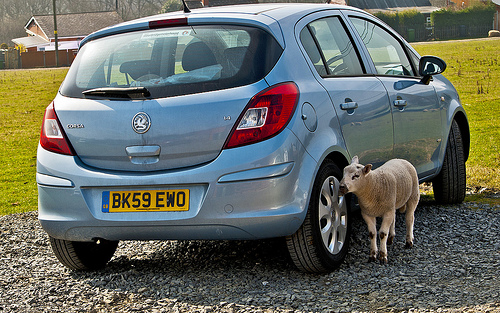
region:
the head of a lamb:
[333, 148, 378, 200]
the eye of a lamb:
[348, 170, 364, 182]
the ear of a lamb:
[360, 160, 378, 177]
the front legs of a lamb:
[357, 203, 397, 264]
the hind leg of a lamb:
[400, 187, 427, 237]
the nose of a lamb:
[336, 178, 351, 193]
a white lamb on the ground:
[332, 152, 429, 268]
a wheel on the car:
[282, 154, 365, 285]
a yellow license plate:
[92, 184, 194, 217]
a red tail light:
[222, 76, 303, 148]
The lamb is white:
[336, 147, 441, 270]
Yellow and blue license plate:
[83, 181, 201, 220]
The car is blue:
[36, 13, 478, 261]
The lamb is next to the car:
[33, 11, 478, 270]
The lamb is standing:
[325, 138, 445, 269]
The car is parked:
[26, 16, 483, 269]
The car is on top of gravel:
[19, 1, 484, 293]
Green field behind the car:
[39, 38, 484, 175]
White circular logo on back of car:
[128, 108, 161, 138]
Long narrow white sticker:
[138, 27, 202, 44]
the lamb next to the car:
[335, 152, 420, 268]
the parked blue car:
[34, 3, 471, 269]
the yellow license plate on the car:
[97, 187, 192, 215]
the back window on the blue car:
[59, 30, 279, 87]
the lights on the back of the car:
[35, 97, 302, 159]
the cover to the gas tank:
[294, 93, 324, 138]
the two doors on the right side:
[293, 1, 452, 176]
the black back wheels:
[40, 165, 360, 275]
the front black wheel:
[441, 122, 472, 210]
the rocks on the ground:
[388, 254, 469, 311]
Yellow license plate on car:
[108, 186, 195, 219]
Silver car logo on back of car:
[128, 111, 155, 136]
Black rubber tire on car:
[286, 239, 348, 272]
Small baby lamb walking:
[336, 158, 421, 268]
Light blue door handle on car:
[337, 96, 364, 117]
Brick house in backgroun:
[8, 12, 75, 66]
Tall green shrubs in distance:
[427, 6, 496, 38]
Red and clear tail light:
[228, 82, 305, 146]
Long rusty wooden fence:
[21, 51, 55, 66]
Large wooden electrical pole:
[52, 1, 59, 50]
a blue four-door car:
[28, 5, 470, 273]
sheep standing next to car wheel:
[277, 126, 425, 268]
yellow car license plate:
[100, 185, 192, 212]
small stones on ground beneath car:
[0, 190, 490, 312]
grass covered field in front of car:
[4, 38, 494, 212]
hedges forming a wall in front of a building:
[379, 3, 496, 40]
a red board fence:
[19, 46, 75, 68]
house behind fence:
[8, 12, 128, 71]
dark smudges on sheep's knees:
[363, 220, 390, 249]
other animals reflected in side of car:
[321, 90, 449, 153]